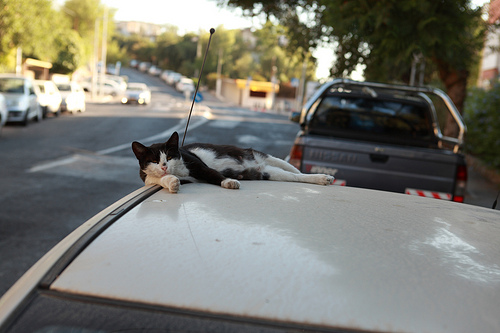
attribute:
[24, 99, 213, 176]
line — white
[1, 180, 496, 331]
car roof — white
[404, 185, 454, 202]
stripes — white, orange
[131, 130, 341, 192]
cat — black, white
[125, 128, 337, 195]
cat — black, white, sleeping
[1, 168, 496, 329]
hood — gray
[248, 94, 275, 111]
cones — caution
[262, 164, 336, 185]
cat leg — white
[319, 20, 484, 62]
leaves — green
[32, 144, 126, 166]
line — white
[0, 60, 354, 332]
road — blacktop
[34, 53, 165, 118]
cars — parked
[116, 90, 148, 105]
headlights — on